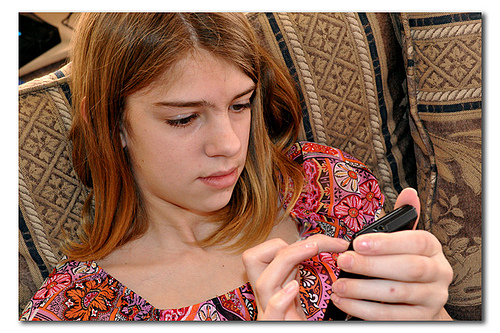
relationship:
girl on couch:
[17, 12, 456, 322] [21, 14, 483, 322]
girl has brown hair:
[17, 12, 456, 322] [61, 14, 303, 261]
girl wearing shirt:
[17, 12, 456, 322] [20, 140, 385, 321]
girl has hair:
[17, 12, 456, 322] [54, 10, 304, 267]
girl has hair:
[17, 12, 456, 322] [19, 15, 484, 320]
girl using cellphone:
[17, 12, 456, 322] [321, 203, 418, 323]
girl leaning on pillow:
[17, 12, 456, 322] [18, 12, 416, 319]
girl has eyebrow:
[17, 12, 456, 322] [230, 83, 260, 103]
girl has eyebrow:
[17, 12, 456, 322] [153, 96, 209, 108]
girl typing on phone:
[17, 12, 456, 322] [337, 190, 450, 317]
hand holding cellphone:
[329, 184, 456, 315] [321, 203, 418, 323]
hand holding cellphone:
[238, 235, 348, 318] [321, 203, 418, 323]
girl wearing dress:
[17, 12, 456, 322] [20, 140, 382, 321]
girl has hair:
[36, 44, 476, 327] [54, 10, 304, 267]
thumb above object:
[383, 180, 426, 232] [320, 197, 426, 319]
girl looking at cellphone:
[17, 12, 456, 322] [321, 202, 419, 321]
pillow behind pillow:
[398, 13, 481, 312] [19, 14, 414, 288]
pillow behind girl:
[398, 13, 481, 312] [17, 12, 456, 322]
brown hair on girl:
[54, 12, 306, 265] [49, 27, 428, 327]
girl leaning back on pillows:
[17, 12, 456, 322] [21, 20, 490, 320]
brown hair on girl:
[54, 12, 306, 265] [17, 12, 456, 322]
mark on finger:
[391, 283, 399, 299] [315, 210, 465, 319]